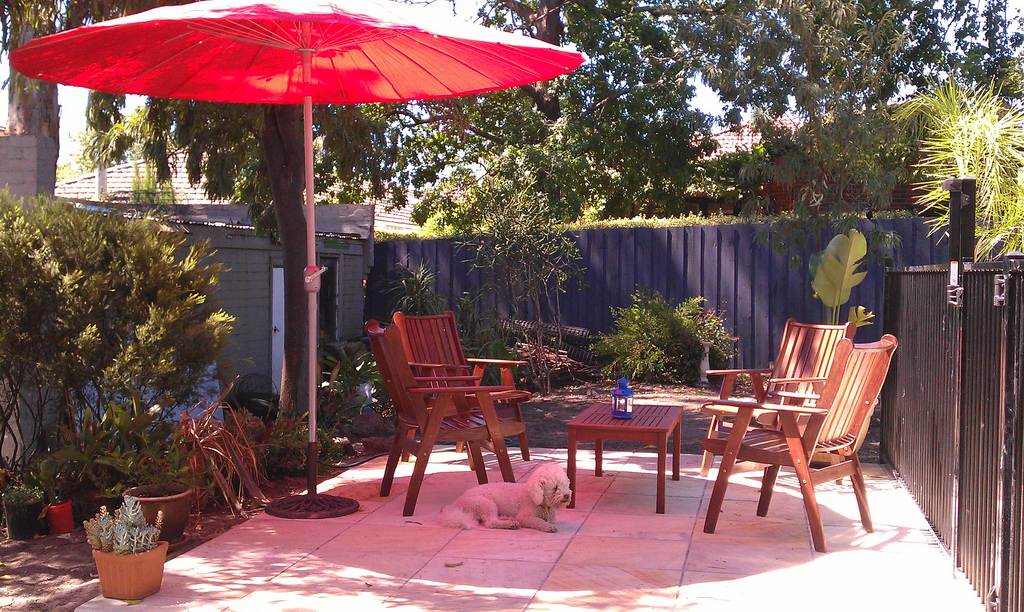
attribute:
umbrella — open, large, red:
[77, 6, 622, 506]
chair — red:
[363, 296, 538, 554]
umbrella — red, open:
[26, 2, 603, 546]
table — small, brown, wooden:
[555, 400, 699, 519]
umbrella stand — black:
[241, 450, 371, 524]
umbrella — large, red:
[39, 6, 599, 487]